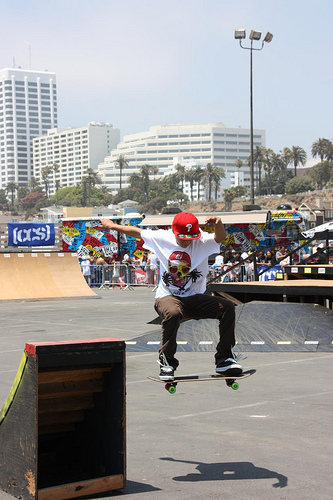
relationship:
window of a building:
[16, 86, 26, 92] [0, 66, 57, 203]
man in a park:
[96, 209, 244, 377] [1, 207, 331, 497]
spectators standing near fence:
[101, 236, 248, 298] [79, 265, 155, 284]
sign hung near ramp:
[6, 219, 56, 248] [3, 246, 99, 307]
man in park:
[96, 209, 244, 377] [1, 207, 331, 497]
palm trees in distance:
[184, 155, 208, 222] [11, 180, 162, 289]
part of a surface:
[262, 338, 330, 425] [0, 285, 332, 498]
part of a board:
[154, 361, 159, 421] [146, 368, 255, 393]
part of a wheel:
[170, 382, 173, 421] [155, 367, 185, 395]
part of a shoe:
[153, 364, 176, 388] [215, 360, 242, 373]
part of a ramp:
[279, 327, 317, 366] [0, 337, 127, 497]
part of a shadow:
[261, 467, 290, 500] [183, 434, 298, 495]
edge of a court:
[309, 322, 331, 435] [261, 344, 306, 355]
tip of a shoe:
[163, 366, 172, 396] [210, 354, 253, 375]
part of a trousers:
[156, 316, 186, 360] [156, 291, 237, 356]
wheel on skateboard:
[163, 379, 185, 407] [148, 364, 289, 387]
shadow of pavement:
[159, 450, 285, 500] [27, 277, 105, 332]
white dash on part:
[115, 340, 324, 347] [261, 467, 290, 500]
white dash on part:
[124, 340, 324, 347] [261, 467, 290, 500]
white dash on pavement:
[124, 340, 324, 347] [183, 378, 329, 493]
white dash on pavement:
[124, 340, 324, 347] [176, 396, 278, 454]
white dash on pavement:
[250, 335, 270, 356] [157, 404, 250, 441]